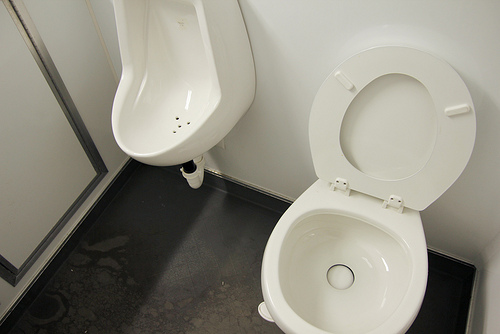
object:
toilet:
[260, 44, 478, 333]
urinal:
[108, 0, 260, 167]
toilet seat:
[306, 44, 477, 213]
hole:
[176, 116, 180, 120]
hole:
[187, 121, 191, 125]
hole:
[178, 125, 181, 129]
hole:
[172, 131, 176, 134]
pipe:
[180, 159, 205, 189]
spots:
[0, 193, 260, 333]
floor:
[0, 168, 481, 334]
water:
[299, 240, 389, 319]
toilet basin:
[259, 179, 429, 333]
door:
[0, 0, 105, 275]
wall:
[0, 0, 500, 266]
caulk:
[87, 0, 119, 87]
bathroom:
[0, 0, 498, 333]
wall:
[77, 0, 497, 268]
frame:
[1, 0, 113, 321]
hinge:
[331, 176, 352, 196]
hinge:
[381, 194, 407, 214]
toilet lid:
[304, 44, 478, 212]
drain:
[172, 116, 191, 134]